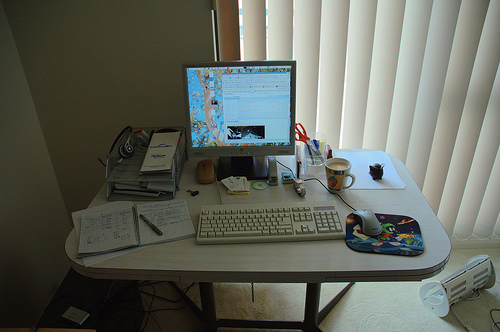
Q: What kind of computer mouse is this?
A: Wired black and silvertone.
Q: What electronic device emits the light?
A: Computer screen.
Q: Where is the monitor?
A: On a small table.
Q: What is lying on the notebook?
A: A pen.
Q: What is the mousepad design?
A: Cartoon character.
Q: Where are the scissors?
A: In a clear container on the table.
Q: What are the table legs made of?
A: Metal.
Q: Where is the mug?
A: Right side of the table.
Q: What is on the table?
A: Computer.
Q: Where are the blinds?
A: Behind table.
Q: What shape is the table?
A: Square.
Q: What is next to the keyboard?
A: Pen and paper.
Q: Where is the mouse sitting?
A: Mouse pad.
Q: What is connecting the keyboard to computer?
A: Wire.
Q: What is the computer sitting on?
A: Table.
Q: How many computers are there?
A: One.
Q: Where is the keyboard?
A: Front of computer.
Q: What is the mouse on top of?
A: Mouse pad.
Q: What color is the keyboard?
A: White.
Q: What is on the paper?
A: Pen.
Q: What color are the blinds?
A: White.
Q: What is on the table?
A: Cup.